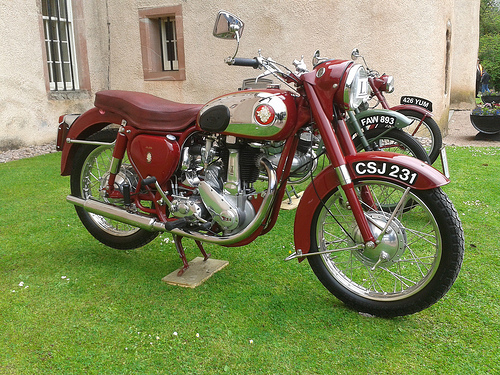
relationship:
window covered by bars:
[155, 15, 178, 72] [155, 16, 173, 67]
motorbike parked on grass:
[232, 41, 445, 175] [119, 283, 296, 345]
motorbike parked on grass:
[200, 55, 436, 225] [119, 283, 296, 345]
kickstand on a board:
[162, 216, 221, 287] [158, 243, 234, 318]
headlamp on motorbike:
[311, 54, 371, 118] [232, 41, 445, 175]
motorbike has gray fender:
[232, 41, 445, 175] [57, 51, 408, 309]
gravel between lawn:
[3, 142, 55, 159] [16, 237, 335, 345]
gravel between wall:
[3, 142, 55, 159] [261, 0, 449, 65]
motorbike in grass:
[54, 11, 463, 319] [2, 230, 484, 365]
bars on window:
[37, 1, 75, 92] [28, 0, 83, 96]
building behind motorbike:
[4, 5, 482, 153] [54, 11, 463, 319]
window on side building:
[140, 18, 183, 75] [4, 5, 482, 153]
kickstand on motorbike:
[175, 203, 205, 270] [54, 11, 463, 319]